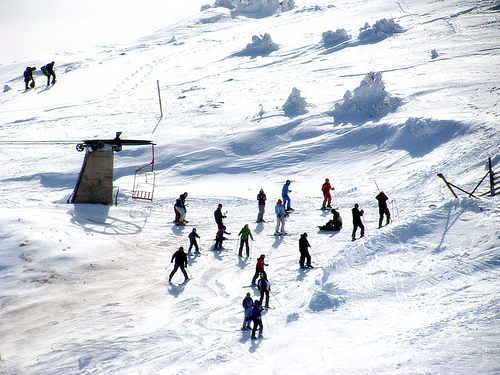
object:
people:
[351, 204, 364, 242]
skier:
[242, 292, 254, 330]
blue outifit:
[242, 296, 253, 327]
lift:
[132, 145, 155, 202]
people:
[23, 66, 37, 91]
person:
[317, 209, 343, 231]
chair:
[131, 168, 154, 201]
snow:
[0, 3, 499, 373]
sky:
[3, 4, 184, 46]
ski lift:
[1, 134, 161, 210]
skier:
[281, 179, 294, 213]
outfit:
[282, 184, 292, 209]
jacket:
[238, 224, 254, 241]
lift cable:
[0, 140, 86, 144]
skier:
[256, 188, 266, 223]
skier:
[321, 178, 335, 208]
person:
[40, 61, 56, 87]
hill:
[0, 1, 498, 371]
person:
[237, 224, 254, 258]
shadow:
[68, 202, 142, 235]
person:
[298, 232, 314, 269]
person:
[168, 247, 189, 283]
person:
[213, 203, 231, 235]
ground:
[0, 2, 497, 373]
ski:
[0, 0, 500, 375]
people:
[374, 191, 390, 229]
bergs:
[333, 70, 401, 115]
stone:
[68, 144, 116, 203]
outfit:
[321, 181, 333, 206]